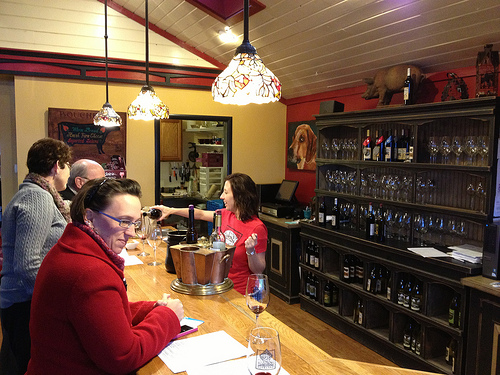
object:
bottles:
[186, 204, 226, 251]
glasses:
[427, 135, 496, 165]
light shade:
[93, 101, 124, 128]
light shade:
[126, 84, 170, 121]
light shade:
[211, 43, 282, 106]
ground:
[417, 161, 469, 223]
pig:
[360, 63, 427, 108]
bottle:
[403, 66, 414, 105]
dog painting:
[288, 124, 317, 171]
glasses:
[326, 169, 435, 205]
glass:
[417, 214, 470, 248]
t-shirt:
[216, 208, 268, 296]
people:
[56, 158, 105, 208]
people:
[0, 137, 74, 375]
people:
[28, 174, 184, 374]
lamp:
[91, 0, 282, 129]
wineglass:
[133, 219, 150, 257]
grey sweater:
[0, 179, 69, 309]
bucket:
[169, 241, 237, 296]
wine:
[142, 207, 162, 219]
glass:
[146, 224, 164, 266]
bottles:
[318, 124, 490, 247]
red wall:
[283, 95, 322, 198]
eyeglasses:
[85, 207, 141, 228]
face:
[95, 193, 142, 255]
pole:
[242, 0, 249, 43]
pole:
[144, 0, 149, 84]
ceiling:
[0, 0, 500, 99]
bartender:
[146, 172, 268, 300]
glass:
[322, 140, 330, 159]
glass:
[331, 138, 341, 159]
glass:
[246, 273, 270, 328]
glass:
[247, 327, 281, 374]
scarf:
[23, 172, 72, 223]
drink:
[135, 207, 153, 257]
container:
[168, 242, 235, 296]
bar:
[0, 0, 500, 375]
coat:
[24, 223, 181, 375]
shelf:
[297, 96, 500, 375]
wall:
[285, 60, 499, 204]